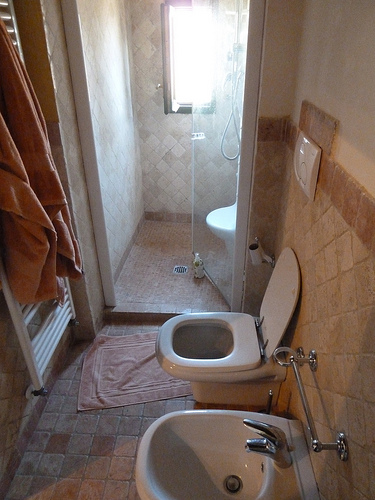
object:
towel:
[76, 323, 182, 426]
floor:
[65, 434, 117, 485]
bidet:
[204, 199, 239, 238]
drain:
[170, 264, 190, 276]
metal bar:
[272, 338, 349, 461]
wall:
[314, 53, 350, 95]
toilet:
[0, 0, 375, 500]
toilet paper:
[245, 240, 274, 274]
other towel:
[0, 5, 87, 282]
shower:
[172, 8, 241, 188]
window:
[156, 0, 247, 118]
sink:
[132, 404, 273, 500]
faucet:
[240, 416, 292, 469]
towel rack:
[0, 0, 79, 404]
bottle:
[189, 250, 206, 279]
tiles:
[45, 418, 114, 432]